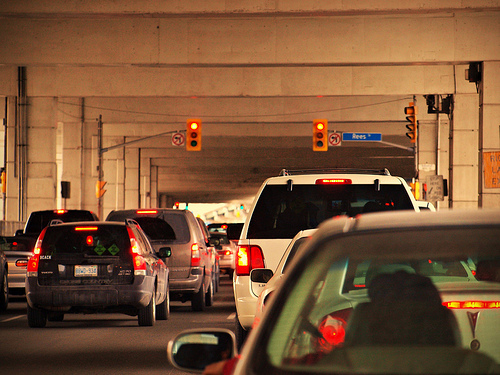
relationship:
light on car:
[174, 100, 211, 155] [312, 237, 427, 319]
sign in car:
[337, 125, 381, 146] [312, 237, 427, 319]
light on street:
[174, 100, 211, 155] [102, 345, 124, 354]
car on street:
[312, 237, 427, 319] [102, 345, 124, 354]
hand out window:
[197, 234, 217, 242] [269, 224, 287, 234]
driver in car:
[368, 268, 411, 294] [312, 237, 427, 319]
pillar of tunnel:
[2, 141, 69, 183] [13, 131, 161, 198]